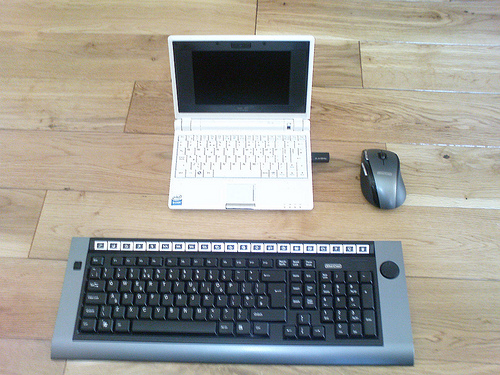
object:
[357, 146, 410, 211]
mouse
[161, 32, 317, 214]
laptop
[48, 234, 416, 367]
keyboard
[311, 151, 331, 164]
usb